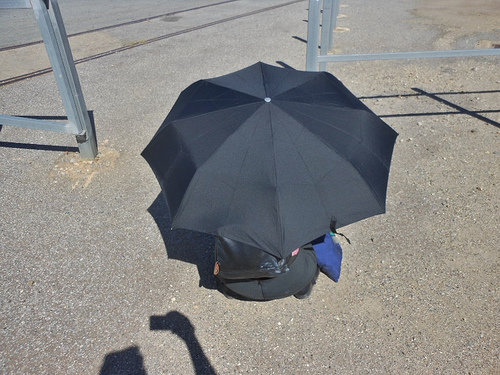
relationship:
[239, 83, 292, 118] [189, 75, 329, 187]
tip on umbrella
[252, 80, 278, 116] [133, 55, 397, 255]
button on umbrella